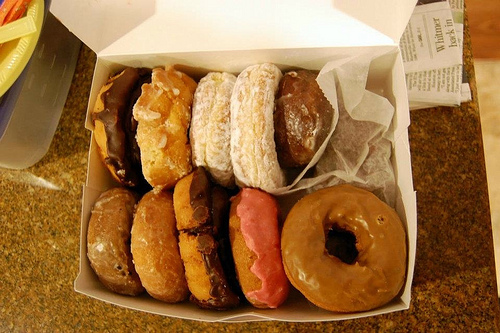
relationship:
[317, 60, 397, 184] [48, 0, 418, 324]
paper on box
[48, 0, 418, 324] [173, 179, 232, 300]
box on dough nut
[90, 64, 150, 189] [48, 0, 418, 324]
frosting on box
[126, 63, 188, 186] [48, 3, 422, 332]
dough nugt on box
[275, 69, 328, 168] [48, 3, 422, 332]
nut on box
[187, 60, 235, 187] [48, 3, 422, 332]
dough nut on box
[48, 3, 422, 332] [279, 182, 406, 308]
box on doughnut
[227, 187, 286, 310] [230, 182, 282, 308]
doughnut on pink frosting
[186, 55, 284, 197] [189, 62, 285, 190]
doughnuts on powder/icing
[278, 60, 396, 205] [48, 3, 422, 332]
paper on box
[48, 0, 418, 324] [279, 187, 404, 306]
box on donut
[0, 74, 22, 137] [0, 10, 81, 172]
cover on bucket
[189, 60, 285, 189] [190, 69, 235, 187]
powder/icing top donut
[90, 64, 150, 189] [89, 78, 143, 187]
frosting on doughnut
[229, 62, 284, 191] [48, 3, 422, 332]
doughnuts in box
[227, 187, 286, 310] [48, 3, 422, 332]
doughnut in box